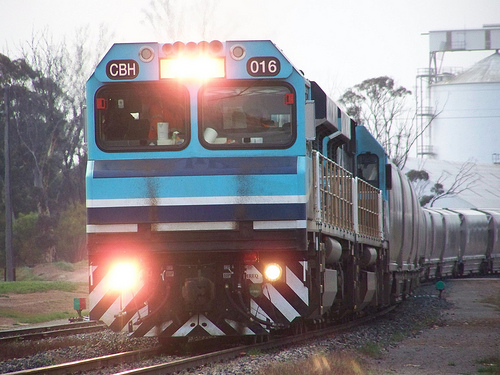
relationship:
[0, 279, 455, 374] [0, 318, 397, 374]
rockes next to tracks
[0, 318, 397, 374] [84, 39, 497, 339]
tracks in front of train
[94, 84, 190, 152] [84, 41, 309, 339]
window on front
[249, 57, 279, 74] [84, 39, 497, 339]
number on train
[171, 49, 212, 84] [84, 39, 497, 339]
light on train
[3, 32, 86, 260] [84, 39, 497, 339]
trees alongside train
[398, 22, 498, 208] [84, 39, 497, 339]
structure behind train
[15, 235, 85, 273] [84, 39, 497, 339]
fence alongside train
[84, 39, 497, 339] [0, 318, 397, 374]
train traveling on tracks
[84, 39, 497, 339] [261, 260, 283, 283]
train has light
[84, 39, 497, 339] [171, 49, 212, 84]
train has light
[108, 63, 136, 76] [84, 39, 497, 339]
letters on train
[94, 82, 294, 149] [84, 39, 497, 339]
window on train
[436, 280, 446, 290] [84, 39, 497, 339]
circle next to train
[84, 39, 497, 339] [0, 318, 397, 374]
train on tracks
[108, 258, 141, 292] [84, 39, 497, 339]
light on train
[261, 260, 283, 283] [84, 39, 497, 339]
light on train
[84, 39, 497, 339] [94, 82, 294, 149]
train has window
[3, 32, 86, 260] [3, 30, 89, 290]
trees in background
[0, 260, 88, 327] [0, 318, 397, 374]
grass next to tracks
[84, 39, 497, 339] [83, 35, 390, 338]
train has engine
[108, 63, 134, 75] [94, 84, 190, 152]
cbh above window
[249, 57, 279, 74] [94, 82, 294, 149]
number above window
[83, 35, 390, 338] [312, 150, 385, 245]
engine has railing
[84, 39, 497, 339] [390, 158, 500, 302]
train pulling cars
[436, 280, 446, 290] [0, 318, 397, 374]
circle beside tracks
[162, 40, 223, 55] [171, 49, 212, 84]
horns above light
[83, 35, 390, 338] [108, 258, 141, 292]
engine has light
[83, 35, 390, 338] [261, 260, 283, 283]
engine has light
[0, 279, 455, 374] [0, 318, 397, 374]
rockes beside tracks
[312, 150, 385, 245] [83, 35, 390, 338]
railing on engine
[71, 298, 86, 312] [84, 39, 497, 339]
reflector beside train